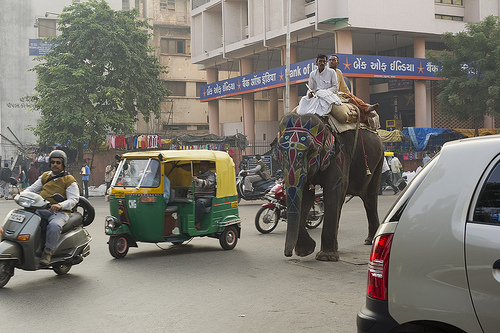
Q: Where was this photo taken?
A: In a city.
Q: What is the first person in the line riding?
A: Motorcycle.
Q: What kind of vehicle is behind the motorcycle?
A: A small van.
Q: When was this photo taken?
A: During the daytime.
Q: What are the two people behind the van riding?
A: An elephant.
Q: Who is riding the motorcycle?
A: A man.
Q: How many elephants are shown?
A: One.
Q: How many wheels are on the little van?
A: Three.